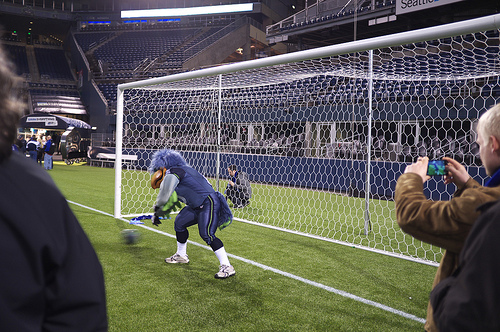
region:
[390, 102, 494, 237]
Man taking a picture with his camera.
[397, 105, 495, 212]
Man taking a picture of the team mascot.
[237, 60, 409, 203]
White netting on the field.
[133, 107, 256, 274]
Mascot on the field.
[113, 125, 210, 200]
Mascot wearing a blue mask.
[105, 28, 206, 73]
No one is sitting in these seats.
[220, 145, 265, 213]
Man crouched behind the goal.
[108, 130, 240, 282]
Mascot reaching for the ball.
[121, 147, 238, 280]
Mascot blocking the ball.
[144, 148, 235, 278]
Team mascot in a feathered costume.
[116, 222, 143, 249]
Ball moving on the ground.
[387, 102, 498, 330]
Man taking a picture.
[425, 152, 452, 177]
Cell phone in photo mode.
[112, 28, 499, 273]
Goal.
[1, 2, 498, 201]
Stadium seating.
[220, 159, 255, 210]
Person kneeling behind the goal.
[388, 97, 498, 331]
Man in a brown jacket.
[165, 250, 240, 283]
Mascot wearing shoes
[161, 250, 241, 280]
Mascot is wearing shoes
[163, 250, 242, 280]
Mascot wearing white and black shoes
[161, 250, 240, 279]
Mascot is wearing white and black shoes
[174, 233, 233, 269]
Mascot wearing socks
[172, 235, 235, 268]
Mascot is wearing white socks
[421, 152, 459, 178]
Person holding a camera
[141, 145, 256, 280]
Mascot standing on the grass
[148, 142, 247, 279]
Mascot is standing on the grass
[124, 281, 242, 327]
The grass is green in color.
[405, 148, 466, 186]
The man is holding a cell phone.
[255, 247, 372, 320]
The grass has a white stripe.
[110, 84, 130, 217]
The fence pole is white.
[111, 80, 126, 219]
The fence pole is made of metal.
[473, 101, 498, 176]
The man's hair is blonde.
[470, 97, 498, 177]
The man's hair is short.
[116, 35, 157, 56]
The seats are blue in color.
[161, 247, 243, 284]
The mascot is wearing tennis shoes.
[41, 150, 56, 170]
The man is wearing blue jeans.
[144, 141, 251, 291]
mascot has blue face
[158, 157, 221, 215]
blue and silver jersey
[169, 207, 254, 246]
blue and gold pants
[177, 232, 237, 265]
mascot has white socks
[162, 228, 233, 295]
mascot has white shoes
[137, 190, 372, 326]
white line near goal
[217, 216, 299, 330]
green grass on field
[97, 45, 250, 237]
white bars on goal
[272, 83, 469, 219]
white mesh net behind mascot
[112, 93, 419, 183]
blue walls behind field